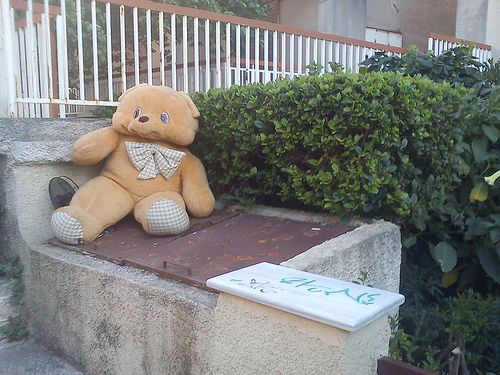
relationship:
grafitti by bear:
[275, 273, 388, 304] [50, 81, 216, 250]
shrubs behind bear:
[199, 50, 498, 227] [50, 81, 216, 250]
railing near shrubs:
[1, 2, 500, 104] [199, 50, 498, 227]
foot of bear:
[145, 196, 191, 235] [50, 81, 216, 250]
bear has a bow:
[50, 81, 216, 250] [124, 139, 186, 180]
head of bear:
[109, 83, 202, 148] [50, 81, 216, 250]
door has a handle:
[118, 211, 358, 289] [161, 257, 197, 276]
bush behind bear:
[199, 50, 498, 227] [50, 81, 216, 250]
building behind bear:
[278, 9, 499, 93] [50, 81, 216, 250]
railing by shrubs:
[1, 2, 500, 104] [199, 50, 498, 227]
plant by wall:
[381, 289, 500, 373] [1, 119, 401, 375]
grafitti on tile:
[275, 273, 388, 304] [206, 259, 405, 334]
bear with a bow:
[50, 81, 216, 250] [124, 139, 186, 180]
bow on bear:
[124, 139, 186, 180] [50, 81, 216, 250]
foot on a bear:
[145, 196, 191, 235] [50, 81, 216, 250]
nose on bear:
[138, 114, 149, 127] [50, 81, 216, 250]